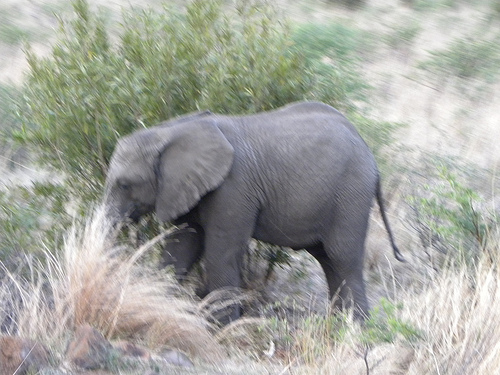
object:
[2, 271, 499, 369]
ground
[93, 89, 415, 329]
elephant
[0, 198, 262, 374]
bush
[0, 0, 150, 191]
bush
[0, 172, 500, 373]
grass